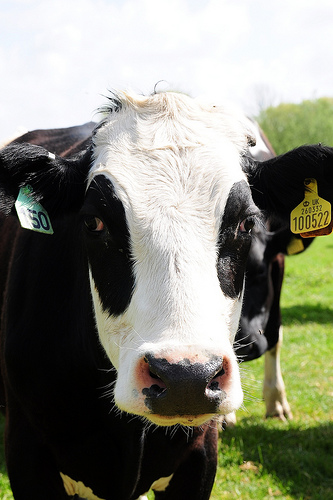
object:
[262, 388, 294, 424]
hoof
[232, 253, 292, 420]
cow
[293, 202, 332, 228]
number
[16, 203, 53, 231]
number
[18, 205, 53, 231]
150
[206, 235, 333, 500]
grass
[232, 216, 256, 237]
left eye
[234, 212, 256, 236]
eyeball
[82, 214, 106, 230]
eyeball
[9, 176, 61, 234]
tag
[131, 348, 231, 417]
nose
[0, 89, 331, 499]
dairy cow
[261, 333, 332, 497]
field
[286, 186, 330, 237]
tag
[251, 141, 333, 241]
cow's ear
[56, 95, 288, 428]
face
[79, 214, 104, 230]
right eye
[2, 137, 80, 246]
ear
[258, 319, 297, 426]
leg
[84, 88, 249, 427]
white hair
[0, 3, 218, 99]
cloud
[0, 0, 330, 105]
sky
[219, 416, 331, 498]
shadow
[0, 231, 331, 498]
ground